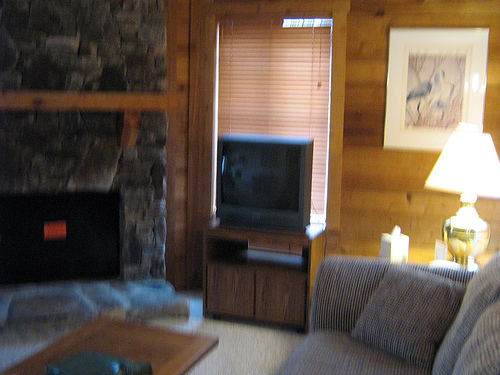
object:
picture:
[381, 27, 491, 153]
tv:
[213, 131, 315, 233]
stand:
[200, 220, 326, 334]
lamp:
[423, 131, 500, 273]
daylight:
[209, 16, 333, 228]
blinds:
[217, 13, 332, 216]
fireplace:
[1, 0, 189, 328]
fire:
[43, 218, 69, 242]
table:
[0, 313, 220, 374]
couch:
[273, 252, 500, 374]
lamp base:
[440, 213, 490, 274]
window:
[203, 9, 347, 233]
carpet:
[0, 315, 307, 374]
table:
[406, 244, 499, 279]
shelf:
[1, 89, 181, 148]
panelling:
[168, 0, 500, 291]